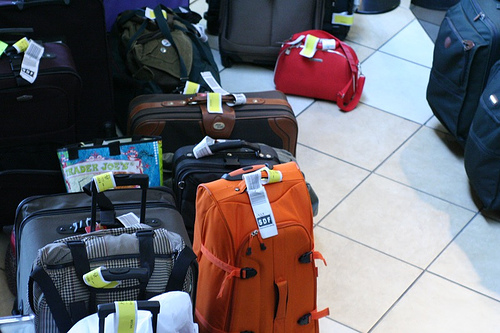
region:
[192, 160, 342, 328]
orange luggage with white tag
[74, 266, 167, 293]
black luggage handle with yellow tag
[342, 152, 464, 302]
diagnal white tile floor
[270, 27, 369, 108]
small red bag with yellow tag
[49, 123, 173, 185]
Trader Joey's plastic bag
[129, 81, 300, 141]
brown and black luggage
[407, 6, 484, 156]
black luggage on a white floor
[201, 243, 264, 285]
orange strap with black buckle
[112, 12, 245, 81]
black and brown bag with black straps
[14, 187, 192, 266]
gray luggage with black zipper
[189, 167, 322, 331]
Orange luggage bag standing up.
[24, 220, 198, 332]
Checkered black and white bag.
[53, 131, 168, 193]
Trader Joe's bag next to luggage.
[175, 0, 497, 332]
White tiled floor where bags are.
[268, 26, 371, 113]
Small red bag with a strap.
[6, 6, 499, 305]
Dark colored bags put together.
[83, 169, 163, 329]
Handles sticking up for easy use.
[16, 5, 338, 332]
Tags on the bag showing where they are going.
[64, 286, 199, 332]
Luggage that is white.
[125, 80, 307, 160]
Two-toned colored luggage.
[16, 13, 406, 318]
a pile of luggage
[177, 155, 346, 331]
an orange suitcase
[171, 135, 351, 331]
two suitcases that roll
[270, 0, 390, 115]
a small red suitcase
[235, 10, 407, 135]
a small red bag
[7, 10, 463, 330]
suitcase on the floor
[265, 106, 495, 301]
a ceramic tile floor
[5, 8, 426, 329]
suitcases that are inside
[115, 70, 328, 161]
a brown and black suitcase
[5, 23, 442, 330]
suitcases that have tags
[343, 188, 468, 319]
tiles on a floor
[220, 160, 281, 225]
luggage handle and tag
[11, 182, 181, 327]
three pieces of luggage lined up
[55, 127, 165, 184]
shopping bag from a well-known store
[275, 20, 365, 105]
small red carry-on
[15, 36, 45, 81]
baggage claim tag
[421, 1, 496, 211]
two black bags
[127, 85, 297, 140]
older style suitcase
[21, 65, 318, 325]
luggage grouped together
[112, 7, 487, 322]
various bags at an airport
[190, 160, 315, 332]
A orange luggage bag.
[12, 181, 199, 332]
A mline of luggage.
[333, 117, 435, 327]
A white tile floor.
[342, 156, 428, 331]
Lines on the floor.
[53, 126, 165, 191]
A trader joes hand bag.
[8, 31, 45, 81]
Tags on the luggage.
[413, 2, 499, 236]
Blue luggage bags.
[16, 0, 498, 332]
Luggage on the tile floor.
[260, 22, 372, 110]
A small red han bag.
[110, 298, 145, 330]
A yellow tag on the handle.